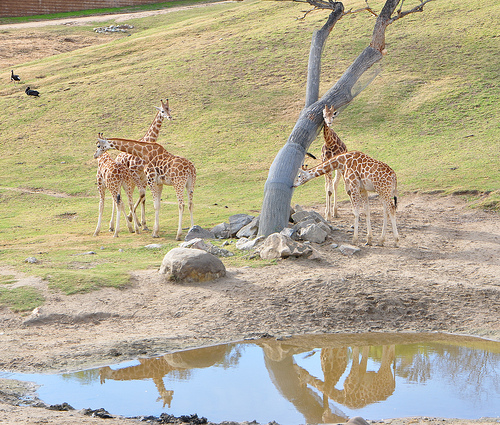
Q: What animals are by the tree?
A: Giraffes.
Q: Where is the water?
A: In the pond.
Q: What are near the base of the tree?
A: Boulders.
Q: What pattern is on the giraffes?
A: Spots.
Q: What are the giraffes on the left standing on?
A: Grass.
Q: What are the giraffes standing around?
A: Tree.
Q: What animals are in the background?
A: Birds.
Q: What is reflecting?
A: Water.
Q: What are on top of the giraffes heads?
A: Horns.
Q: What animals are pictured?
A: Giraffes.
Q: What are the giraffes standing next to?
A: Tree.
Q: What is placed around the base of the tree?
A: Rocks.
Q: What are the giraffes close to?
A: Tree.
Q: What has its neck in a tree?
A: Giraffe.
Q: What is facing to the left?
A: Giraffe.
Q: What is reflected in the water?
A: Giraffe.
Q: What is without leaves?
A: Tree.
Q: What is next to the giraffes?
A: Waterhole.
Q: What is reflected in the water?
A: Giraffes.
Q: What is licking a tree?
A: Giraffe.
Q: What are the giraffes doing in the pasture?
A: Walking.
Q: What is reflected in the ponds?
A: Giraffes.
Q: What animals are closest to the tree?
A: Giraffes.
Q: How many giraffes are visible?
A: 5.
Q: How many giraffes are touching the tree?
A: 2.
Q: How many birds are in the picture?
A: 2.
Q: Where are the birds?
A: Far left.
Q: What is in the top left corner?
A: Brick wall.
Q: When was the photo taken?
A: During the day.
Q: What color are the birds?
A: Black.